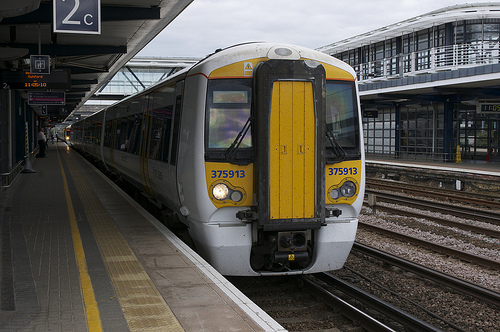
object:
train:
[67, 40, 369, 278]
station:
[1, 0, 499, 331]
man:
[35, 126, 49, 157]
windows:
[414, 32, 430, 45]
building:
[311, 1, 500, 167]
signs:
[51, 0, 104, 36]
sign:
[17, 72, 52, 91]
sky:
[134, 0, 500, 56]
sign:
[27, 54, 52, 75]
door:
[265, 77, 317, 222]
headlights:
[340, 179, 358, 198]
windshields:
[321, 79, 358, 161]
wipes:
[325, 131, 340, 157]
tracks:
[321, 240, 499, 331]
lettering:
[81, 11, 95, 27]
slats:
[256, 219, 327, 232]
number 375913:
[326, 165, 359, 176]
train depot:
[0, 0, 293, 331]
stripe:
[54, 141, 110, 331]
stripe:
[72, 150, 296, 331]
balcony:
[350, 41, 499, 85]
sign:
[243, 60, 255, 71]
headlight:
[211, 182, 230, 201]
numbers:
[210, 169, 217, 179]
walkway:
[0, 140, 291, 332]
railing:
[352, 41, 500, 84]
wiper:
[224, 118, 249, 155]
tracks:
[355, 189, 500, 237]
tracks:
[354, 200, 500, 272]